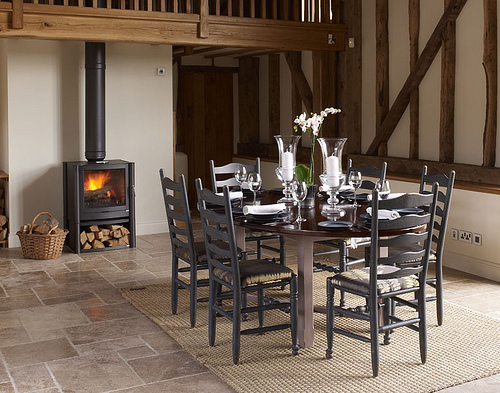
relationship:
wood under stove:
[79, 223, 133, 251] [61, 159, 137, 255]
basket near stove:
[15, 210, 69, 260] [61, 159, 137, 255]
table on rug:
[199, 184, 431, 351] [115, 259, 500, 392]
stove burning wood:
[61, 153, 142, 254] [79, 223, 133, 251]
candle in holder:
[282, 149, 295, 183] [274, 132, 299, 208]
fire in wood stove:
[83, 172, 120, 206] [61, 153, 142, 254]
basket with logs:
[15, 210, 69, 260] [22, 221, 62, 233]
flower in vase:
[293, 101, 343, 182] [299, 180, 318, 212]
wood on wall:
[372, 1, 391, 157] [234, 4, 499, 282]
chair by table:
[159, 169, 252, 325] [199, 184, 431, 351]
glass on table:
[234, 164, 249, 212] [199, 184, 431, 351]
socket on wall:
[472, 231, 484, 245] [234, 4, 499, 282]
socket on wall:
[457, 226, 474, 243] [234, 4, 499, 282]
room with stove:
[2, 3, 498, 392] [61, 159, 137, 255]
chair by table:
[324, 180, 441, 379] [199, 184, 431, 351]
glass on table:
[248, 170, 263, 207] [199, 184, 431, 351]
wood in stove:
[84, 185, 118, 207] [61, 159, 137, 255]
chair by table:
[363, 164, 456, 333] [199, 184, 431, 351]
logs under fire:
[84, 185, 118, 207] [83, 172, 120, 206]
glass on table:
[289, 178, 309, 227] [199, 184, 431, 351]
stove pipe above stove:
[84, 40, 110, 164] [61, 159, 137, 255]